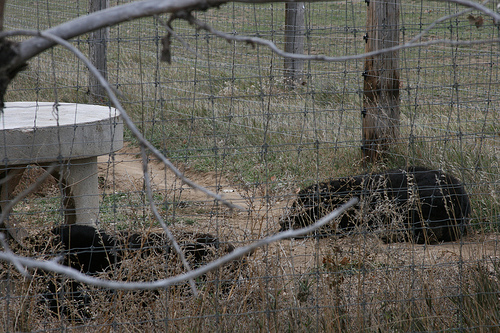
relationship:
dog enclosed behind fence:
[280, 164, 468, 248] [1, 0, 499, 333]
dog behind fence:
[280, 164, 468, 248] [1, 0, 499, 333]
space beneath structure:
[6, 165, 71, 240] [2, 100, 125, 265]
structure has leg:
[2, 100, 125, 265] [39, 157, 100, 231]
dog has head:
[280, 164, 468, 248] [281, 177, 334, 239]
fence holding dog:
[1, 0, 499, 333] [280, 164, 468, 248]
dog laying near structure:
[280, 164, 468, 248] [2, 100, 125, 265]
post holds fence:
[364, 2, 401, 163] [1, 0, 499, 333]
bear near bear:
[274, 165, 477, 250] [16, 220, 254, 320]